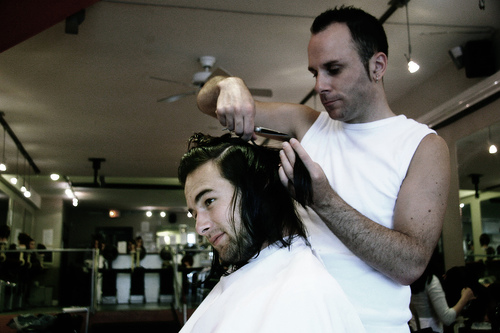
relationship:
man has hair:
[160, 125, 367, 333] [291, 153, 313, 203]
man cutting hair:
[160, 125, 367, 333] [172, 126, 309, 273]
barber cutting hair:
[195, 0, 461, 333] [171, 124, 317, 261]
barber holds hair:
[195, 0, 461, 333] [265, 123, 320, 214]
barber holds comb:
[214, 5, 442, 329] [256, 122, 291, 144]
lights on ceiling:
[46, 171, 88, 222] [15, 121, 135, 227]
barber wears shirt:
[195, 0, 461, 333] [285, 108, 440, 331]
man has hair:
[160, 125, 367, 333] [171, 126, 302, 243]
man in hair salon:
[160, 125, 367, 333] [7, 6, 489, 327]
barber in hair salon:
[195, 0, 461, 333] [7, 6, 489, 327]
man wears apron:
[160, 125, 371, 330] [172, 227, 376, 332]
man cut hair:
[160, 125, 367, 333] [178, 132, 313, 250]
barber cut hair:
[195, 0, 461, 333] [171, 131, 317, 254]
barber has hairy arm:
[195, 0, 461, 333] [307, 165, 394, 250]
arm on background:
[429, 277, 472, 327] [1, 155, 499, 323]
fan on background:
[148, 52, 274, 106] [15, 42, 293, 83]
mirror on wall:
[452, 125, 499, 265] [454, 106, 498, 257]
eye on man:
[202, 197, 219, 205] [160, 125, 371, 330]